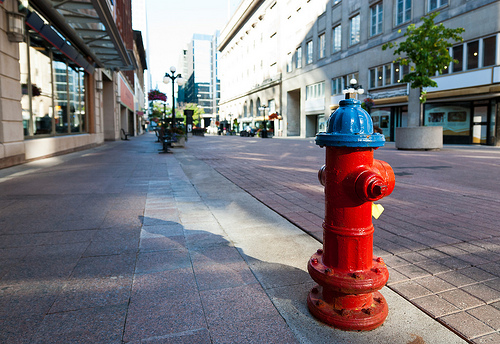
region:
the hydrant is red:
[292, 150, 472, 330]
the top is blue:
[300, 79, 393, 151]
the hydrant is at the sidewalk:
[184, 37, 419, 340]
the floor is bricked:
[21, 163, 202, 339]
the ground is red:
[29, 169, 156, 338]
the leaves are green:
[402, 30, 442, 80]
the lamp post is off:
[147, 57, 199, 134]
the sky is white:
[153, 29, 173, 51]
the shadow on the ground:
[117, 172, 335, 337]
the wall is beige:
[6, 87, 42, 152]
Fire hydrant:
[308, 67, 434, 334]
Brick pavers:
[88, 196, 377, 268]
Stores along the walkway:
[219, 85, 497, 217]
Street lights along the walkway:
[159, 55, 236, 203]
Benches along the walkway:
[152, 101, 194, 174]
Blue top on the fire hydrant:
[312, 80, 395, 148]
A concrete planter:
[387, 102, 474, 167]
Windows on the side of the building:
[28, 57, 86, 103]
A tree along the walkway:
[396, 37, 448, 114]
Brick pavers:
[145, 149, 242, 308]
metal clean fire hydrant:
[306, 91, 396, 331]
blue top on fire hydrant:
[315, 97, 386, 148]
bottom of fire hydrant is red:
[305, 146, 395, 331]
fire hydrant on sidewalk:
[0, 130, 475, 342]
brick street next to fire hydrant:
[180, 131, 499, 342]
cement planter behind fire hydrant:
[394, 125, 443, 150]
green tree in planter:
[382, 11, 465, 124]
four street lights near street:
[158, 65, 365, 137]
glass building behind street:
[176, 28, 221, 133]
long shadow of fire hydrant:
[139, 213, 319, 320]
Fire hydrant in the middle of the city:
[305, 68, 415, 342]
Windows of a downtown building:
[16, 36, 109, 149]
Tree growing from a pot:
[396, 20, 463, 175]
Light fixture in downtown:
[158, 65, 192, 106]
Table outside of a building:
[142, 117, 209, 150]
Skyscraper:
[178, 33, 226, 123]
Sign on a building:
[366, 84, 413, 107]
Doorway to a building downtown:
[98, 78, 124, 141]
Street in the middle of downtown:
[214, 126, 311, 225]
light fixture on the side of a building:
[6, 5, 28, 44]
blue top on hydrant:
[314, 98, 405, 166]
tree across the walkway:
[398, 20, 463, 226]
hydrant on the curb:
[256, 167, 398, 339]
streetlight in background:
[163, 51, 201, 152]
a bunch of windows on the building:
[289, 18, 358, 75]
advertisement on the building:
[426, 96, 492, 157]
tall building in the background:
[184, 25, 244, 145]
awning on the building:
[17, 2, 142, 133]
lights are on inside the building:
[373, 61, 402, 87]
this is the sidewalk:
[108, 168, 188, 334]